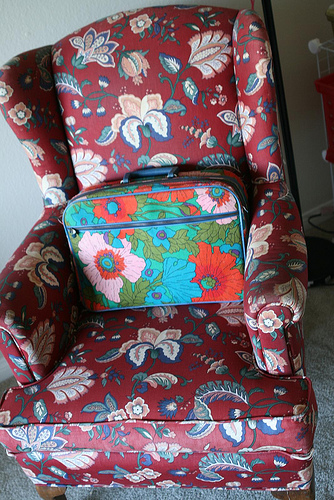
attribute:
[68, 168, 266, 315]
briefcase — small, floral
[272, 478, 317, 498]
leg — wooden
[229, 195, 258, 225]
zipper — metal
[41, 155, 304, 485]
chair — floral, upholstered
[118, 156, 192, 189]
handle — blue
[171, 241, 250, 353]
flower — orange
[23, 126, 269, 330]
suitcase — small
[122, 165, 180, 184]
handle — blue